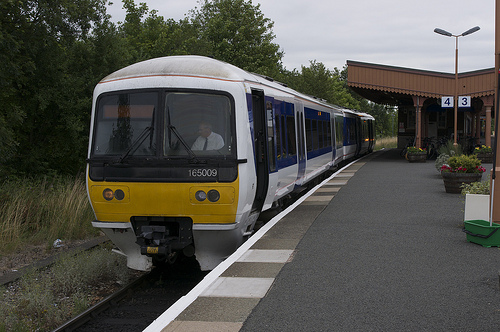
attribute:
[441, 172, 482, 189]
barrel — brown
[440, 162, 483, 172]
flowers — pink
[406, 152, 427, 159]
barrel — brown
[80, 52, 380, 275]
train — brown, white, commuter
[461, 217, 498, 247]
bucket — rectangular, green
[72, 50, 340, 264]
train — white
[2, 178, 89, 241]
grass — tall, brown, green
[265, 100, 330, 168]
window trim — dark blue